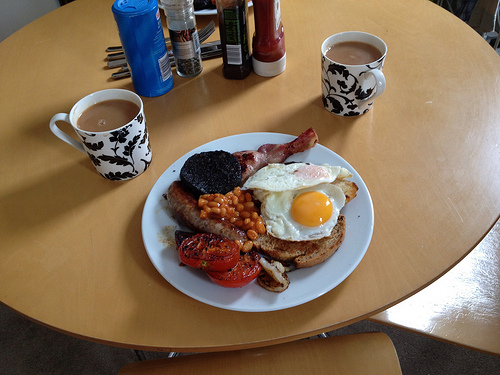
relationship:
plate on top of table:
[139, 129, 375, 312] [0, 3, 498, 374]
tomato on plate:
[178, 234, 240, 270] [139, 129, 375, 312]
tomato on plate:
[209, 253, 260, 285] [139, 129, 375, 312]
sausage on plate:
[178, 130, 319, 196] [139, 129, 375, 312]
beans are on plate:
[195, 186, 265, 240] [139, 129, 375, 312]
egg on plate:
[260, 183, 351, 240] [139, 129, 375, 312]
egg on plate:
[239, 157, 341, 194] [139, 129, 375, 312]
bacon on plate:
[260, 123, 318, 160] [139, 129, 375, 312]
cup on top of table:
[50, 86, 152, 182] [0, 3, 498, 374]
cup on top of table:
[318, 29, 386, 118] [0, 3, 498, 374]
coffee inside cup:
[79, 97, 141, 134] [50, 86, 152, 182]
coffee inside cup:
[330, 39, 381, 66] [318, 29, 386, 118]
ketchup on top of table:
[251, 0, 284, 77] [0, 3, 498, 374]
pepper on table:
[164, 0, 201, 80] [0, 3, 498, 374]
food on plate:
[166, 129, 353, 290] [139, 129, 375, 312]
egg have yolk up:
[260, 183, 351, 240] [294, 192, 332, 227]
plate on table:
[139, 129, 375, 312] [0, 3, 498, 374]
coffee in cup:
[79, 97, 141, 134] [50, 86, 152, 182]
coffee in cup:
[330, 39, 381, 66] [318, 29, 386, 118]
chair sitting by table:
[118, 333, 402, 374] [0, 3, 498, 374]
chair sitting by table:
[363, 214, 499, 354] [0, 3, 498, 374]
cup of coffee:
[50, 86, 152, 182] [79, 97, 141, 134]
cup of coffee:
[318, 29, 386, 118] [330, 39, 381, 66]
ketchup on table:
[251, 0, 284, 77] [0, 3, 498, 374]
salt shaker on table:
[113, 1, 176, 101] [0, 3, 498, 374]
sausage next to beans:
[178, 130, 319, 196] [195, 186, 265, 240]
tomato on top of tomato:
[178, 234, 240, 270] [209, 253, 260, 285]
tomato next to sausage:
[178, 234, 240, 270] [178, 130, 319, 196]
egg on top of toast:
[260, 183, 351, 240] [167, 181, 345, 265]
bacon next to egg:
[260, 123, 318, 160] [239, 157, 341, 194]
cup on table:
[50, 86, 152, 182] [0, 3, 498, 374]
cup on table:
[318, 29, 386, 118] [0, 3, 498, 374]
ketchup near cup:
[251, 0, 284, 77] [318, 29, 386, 118]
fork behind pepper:
[105, 21, 217, 59] [164, 0, 201, 80]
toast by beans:
[167, 181, 345, 265] [195, 186, 265, 240]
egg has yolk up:
[260, 183, 351, 240] [294, 192, 332, 227]